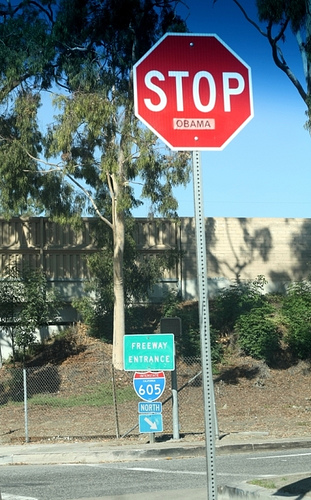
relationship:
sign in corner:
[126, 23, 260, 491] [165, 447, 289, 499]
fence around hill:
[12, 366, 129, 440] [17, 285, 309, 425]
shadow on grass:
[276, 476, 309, 497] [251, 464, 309, 496]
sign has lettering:
[123, 24, 263, 155] [142, 58, 248, 116]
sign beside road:
[134, 410, 171, 433] [8, 450, 310, 495]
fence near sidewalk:
[12, 366, 129, 440] [8, 455, 206, 495]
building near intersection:
[5, 216, 304, 299] [5, 330, 300, 499]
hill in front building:
[0, 281, 311, 431] [5, 216, 304, 299]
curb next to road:
[19, 431, 306, 456] [8, 450, 310, 495]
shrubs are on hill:
[221, 272, 306, 362] [17, 285, 309, 425]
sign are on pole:
[132, 371, 167, 403] [147, 432, 159, 446]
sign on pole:
[132, 371, 167, 403] [147, 432, 159, 446]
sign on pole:
[136, 402, 168, 414] [147, 432, 159, 446]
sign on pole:
[123, 333, 175, 372] [147, 432, 159, 446]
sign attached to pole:
[123, 24, 263, 155] [188, 150, 227, 500]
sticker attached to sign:
[170, 115, 220, 132] [123, 24, 263, 155]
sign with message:
[123, 24, 263, 155] [170, 115, 220, 132]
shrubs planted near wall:
[221, 272, 306, 362] [5, 216, 304, 299]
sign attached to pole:
[132, 371, 167, 403] [147, 432, 159, 446]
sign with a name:
[130, 371, 170, 403] [137, 382, 165, 397]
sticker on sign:
[170, 115, 220, 132] [132, 30, 253, 155]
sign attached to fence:
[130, 371, 170, 403] [7, 363, 251, 446]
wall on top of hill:
[5, 216, 304, 299] [67, 281, 296, 431]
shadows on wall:
[5, 216, 304, 299] [1, 214, 284, 316]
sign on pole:
[134, 410, 171, 433] [183, 149, 239, 496]